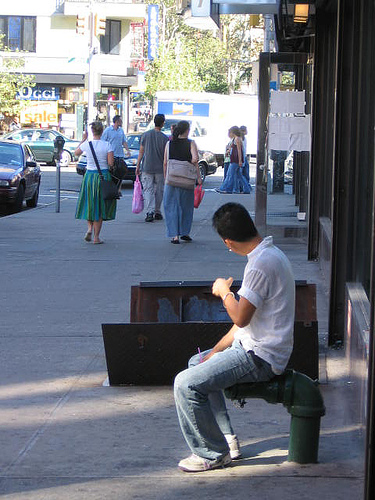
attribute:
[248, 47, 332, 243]
door — glass, shop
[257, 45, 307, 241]
glass door — open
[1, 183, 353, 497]
sidewalk — gray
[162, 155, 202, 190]
bag — tan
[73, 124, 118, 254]
lady — green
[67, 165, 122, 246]
green skirt — blue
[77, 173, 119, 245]
skirt — green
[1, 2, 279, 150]
buildings — white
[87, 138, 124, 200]
bag — black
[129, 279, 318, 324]
door — open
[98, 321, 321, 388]
door — open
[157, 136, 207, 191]
bag — large